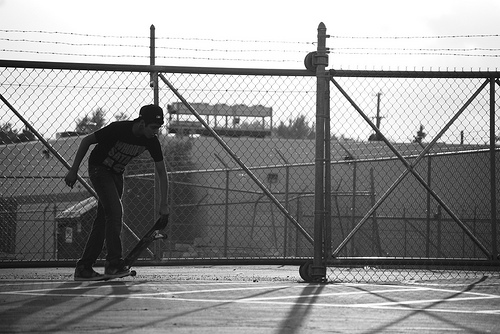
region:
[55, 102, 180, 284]
Boy is skateboarding.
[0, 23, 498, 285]
Barbed Wire Fence.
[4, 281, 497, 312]
White lines painted on blacktop.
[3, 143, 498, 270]
The building is painted white.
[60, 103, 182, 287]
Boy is flipping skateboard up.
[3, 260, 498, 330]
The ground is black top.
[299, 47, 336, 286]
There are wheels on the gate door.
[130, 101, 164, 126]
The hat is dark colored.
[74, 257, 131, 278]
The shoes are high tops.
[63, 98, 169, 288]
The boy is wearing a dark shirt.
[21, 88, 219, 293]
man skate boarding on ground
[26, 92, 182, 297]
man holding skate board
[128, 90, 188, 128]
base ball hat on backwards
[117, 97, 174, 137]
hat on top of man's head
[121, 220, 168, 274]
black skate board on ground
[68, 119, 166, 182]
black t-shirt with writing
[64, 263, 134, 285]
skate shoes on man's feet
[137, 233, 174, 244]
black skate wheels on feet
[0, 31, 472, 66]
barbed wire on top of fence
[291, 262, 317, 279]
wheel on bottom of fence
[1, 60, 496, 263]
chain link fence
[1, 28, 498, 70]
barb wire on top of gate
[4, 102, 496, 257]
white building in the back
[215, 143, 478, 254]
metal poles next to building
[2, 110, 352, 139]
top of trees behind building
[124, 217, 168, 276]
black skateboard tilted up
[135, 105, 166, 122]
black hat on guy's head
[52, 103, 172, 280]
guy holding skateboard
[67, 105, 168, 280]
guy performing a skateboarding trick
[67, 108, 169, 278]
guy wearing a black shirt and jeans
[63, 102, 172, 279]
young man is skateboarding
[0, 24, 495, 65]
three rows on barbed wire on top of a fence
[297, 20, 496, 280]
sliding gate with wheels on fence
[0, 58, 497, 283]
chain link fence around lot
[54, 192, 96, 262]
dumpster is behind the fence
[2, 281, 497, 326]
shadow of fence on the ground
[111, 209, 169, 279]
skateboard is tipped up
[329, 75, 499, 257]
support beams on fence make an x shape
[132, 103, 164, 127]
black baseball cap is on backwards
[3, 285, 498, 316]
white lines painted on asphalt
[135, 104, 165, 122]
a black cap on a man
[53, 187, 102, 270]
a dumpster behind a man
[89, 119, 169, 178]
a black shirt with words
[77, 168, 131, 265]
jeans on a man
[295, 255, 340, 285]
a wheel on a fence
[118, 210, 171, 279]
a skateboard in a man's hand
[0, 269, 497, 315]
white striped lines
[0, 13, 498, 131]
a gray sky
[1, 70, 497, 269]
a chain link fence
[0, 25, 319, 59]
barbed wire on top of a fence